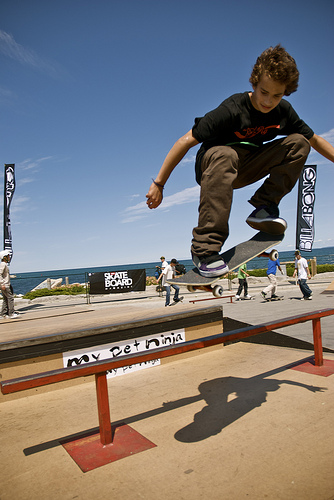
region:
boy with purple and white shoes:
[181, 256, 231, 284]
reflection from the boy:
[161, 382, 285, 449]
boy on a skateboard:
[178, 48, 287, 287]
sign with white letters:
[67, 269, 151, 288]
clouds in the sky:
[102, 184, 199, 209]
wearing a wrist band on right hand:
[138, 171, 173, 195]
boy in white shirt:
[145, 247, 184, 305]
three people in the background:
[237, 256, 325, 306]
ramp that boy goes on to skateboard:
[1, 308, 333, 375]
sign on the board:
[61, 328, 184, 383]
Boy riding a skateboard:
[164, 44, 311, 291]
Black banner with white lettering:
[83, 261, 149, 298]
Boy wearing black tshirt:
[214, 42, 307, 148]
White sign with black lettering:
[113, 332, 182, 356]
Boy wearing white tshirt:
[292, 248, 313, 295]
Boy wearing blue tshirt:
[264, 249, 281, 296]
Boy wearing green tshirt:
[237, 262, 251, 279]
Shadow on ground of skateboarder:
[163, 364, 279, 452]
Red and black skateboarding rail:
[69, 356, 133, 467]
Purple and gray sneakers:
[183, 251, 231, 279]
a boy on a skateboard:
[137, 39, 318, 296]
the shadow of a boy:
[158, 368, 330, 448]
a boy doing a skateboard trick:
[143, 34, 332, 412]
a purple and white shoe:
[186, 249, 236, 280]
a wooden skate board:
[165, 235, 293, 294]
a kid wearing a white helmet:
[1, 244, 13, 264]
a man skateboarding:
[292, 247, 318, 304]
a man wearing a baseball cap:
[289, 247, 303, 264]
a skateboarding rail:
[4, 302, 332, 400]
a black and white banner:
[296, 159, 318, 255]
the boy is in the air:
[139, 30, 315, 310]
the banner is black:
[89, 270, 145, 290]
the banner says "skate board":
[94, 266, 146, 295]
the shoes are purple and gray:
[194, 257, 228, 280]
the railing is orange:
[54, 367, 156, 441]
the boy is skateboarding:
[153, 86, 314, 304]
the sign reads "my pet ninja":
[67, 330, 184, 354]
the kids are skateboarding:
[253, 255, 310, 300]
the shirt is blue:
[265, 256, 277, 271]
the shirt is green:
[235, 265, 255, 285]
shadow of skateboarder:
[162, 376, 325, 442]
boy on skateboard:
[147, 48, 333, 294]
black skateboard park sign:
[87, 268, 146, 291]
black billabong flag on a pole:
[297, 165, 316, 250]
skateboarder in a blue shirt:
[261, 259, 282, 301]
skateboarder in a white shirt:
[152, 256, 182, 303]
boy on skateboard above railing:
[145, 44, 331, 274]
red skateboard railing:
[1, 306, 333, 471]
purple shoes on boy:
[187, 246, 219, 265]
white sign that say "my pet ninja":
[61, 327, 182, 364]